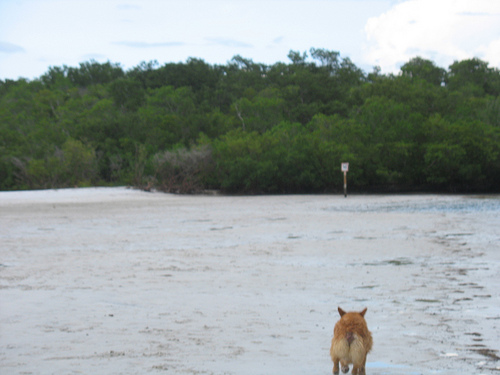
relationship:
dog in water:
[324, 303, 376, 373] [1, 193, 498, 373]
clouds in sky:
[354, 7, 498, 58] [0, 5, 498, 74]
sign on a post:
[332, 147, 374, 214] [338, 180, 354, 190]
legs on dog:
[330, 357, 369, 374] [324, 303, 376, 373]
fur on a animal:
[339, 323, 364, 359] [328, 306, 373, 374]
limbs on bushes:
[127, 152, 217, 190] [110, 98, 290, 189]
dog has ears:
[312, 280, 398, 372] [325, 302, 350, 320]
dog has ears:
[312, 280, 398, 372] [359, 300, 376, 312]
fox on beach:
[328, 306, 372, 373] [67, 128, 347, 373]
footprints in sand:
[427, 221, 499, 370] [0, 181, 497, 373]